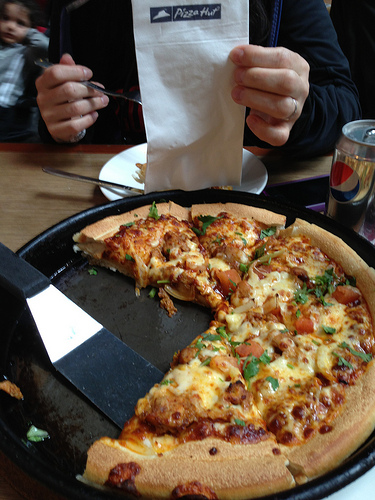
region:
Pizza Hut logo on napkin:
[148, 2, 237, 29]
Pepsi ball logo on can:
[326, 155, 364, 213]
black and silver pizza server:
[0, 243, 180, 445]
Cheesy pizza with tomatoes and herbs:
[68, 188, 366, 488]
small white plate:
[91, 130, 290, 211]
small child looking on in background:
[0, 3, 53, 117]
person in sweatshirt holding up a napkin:
[32, 0, 369, 158]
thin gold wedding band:
[279, 96, 311, 127]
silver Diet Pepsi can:
[322, 108, 370, 243]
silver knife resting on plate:
[36, 158, 155, 202]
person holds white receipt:
[110, 7, 260, 202]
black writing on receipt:
[154, 6, 224, 39]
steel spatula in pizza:
[11, 262, 158, 430]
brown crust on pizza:
[90, 218, 367, 469]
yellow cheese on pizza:
[144, 301, 287, 408]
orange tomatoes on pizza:
[218, 317, 317, 409]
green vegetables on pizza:
[151, 294, 311, 427]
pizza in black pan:
[38, 213, 363, 485]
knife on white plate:
[89, 134, 268, 228]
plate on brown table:
[113, 143, 269, 218]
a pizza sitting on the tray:
[35, 212, 374, 495]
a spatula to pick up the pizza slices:
[6, 260, 160, 412]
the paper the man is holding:
[129, 1, 250, 190]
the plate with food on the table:
[95, 131, 267, 202]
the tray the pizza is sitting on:
[5, 188, 373, 496]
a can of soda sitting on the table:
[329, 115, 374, 244]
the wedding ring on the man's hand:
[285, 98, 300, 125]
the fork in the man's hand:
[36, 56, 154, 119]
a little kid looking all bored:
[2, 5, 49, 126]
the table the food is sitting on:
[1, 141, 325, 218]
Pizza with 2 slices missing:
[72, 201, 374, 499]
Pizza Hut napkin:
[128, 1, 244, 192]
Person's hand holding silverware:
[34, 52, 142, 139]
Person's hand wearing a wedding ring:
[228, 44, 310, 149]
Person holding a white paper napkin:
[35, 1, 358, 192]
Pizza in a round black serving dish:
[3, 186, 374, 498]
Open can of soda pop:
[324, 117, 373, 242]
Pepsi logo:
[327, 159, 360, 204]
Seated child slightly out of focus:
[1, 1, 48, 110]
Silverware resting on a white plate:
[40, 140, 268, 202]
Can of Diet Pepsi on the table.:
[324, 119, 373, 245]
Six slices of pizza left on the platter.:
[72, 201, 373, 497]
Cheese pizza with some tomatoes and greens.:
[74, 202, 374, 499]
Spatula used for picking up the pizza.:
[1, 240, 164, 429]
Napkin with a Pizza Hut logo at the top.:
[132, 0, 248, 193]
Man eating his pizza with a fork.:
[35, 53, 141, 140]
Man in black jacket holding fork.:
[33, 0, 360, 148]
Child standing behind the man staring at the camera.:
[0, 0, 48, 144]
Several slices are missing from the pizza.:
[75, 202, 374, 499]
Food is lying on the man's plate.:
[96, 139, 267, 199]